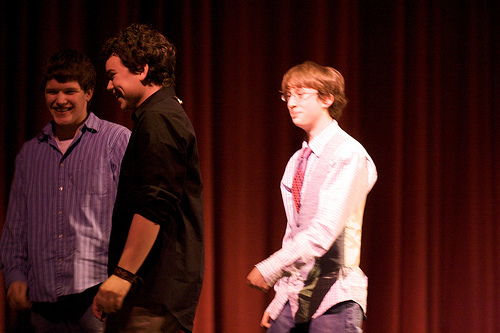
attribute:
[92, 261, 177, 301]
band — black, red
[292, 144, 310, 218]
tie — red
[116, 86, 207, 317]
shirt — rolled up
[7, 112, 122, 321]
shirt — button down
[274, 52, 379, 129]
hair — shaggy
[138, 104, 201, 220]
shirt — black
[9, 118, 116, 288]
shirt — button down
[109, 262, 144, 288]
band — brown, leather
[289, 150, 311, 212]
tie — red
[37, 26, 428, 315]
men — young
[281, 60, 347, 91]
hair — auburn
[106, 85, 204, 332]
black shirt — untucked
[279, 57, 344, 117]
hair — red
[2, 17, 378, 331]
men — young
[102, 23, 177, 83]
curly hair — brown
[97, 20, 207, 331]
man — young, laughing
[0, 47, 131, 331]
man — young, laughing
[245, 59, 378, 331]
man — young, amused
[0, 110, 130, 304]
shirt — button down, blue, white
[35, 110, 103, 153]
collar — unbuttoned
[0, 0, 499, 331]
curtains — red, shadowed